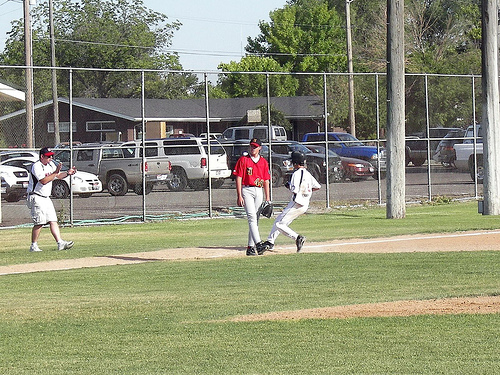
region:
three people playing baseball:
[12, 120, 353, 283]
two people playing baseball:
[213, 116, 340, 296]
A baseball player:
[217, 123, 275, 255]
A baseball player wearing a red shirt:
[225, 128, 277, 255]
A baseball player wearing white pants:
[219, 130, 271, 271]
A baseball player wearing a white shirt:
[271, 125, 320, 269]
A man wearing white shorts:
[17, 137, 81, 277]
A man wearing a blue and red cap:
[20, 138, 77, 245]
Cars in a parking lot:
[54, 121, 234, 204]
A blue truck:
[307, 117, 401, 185]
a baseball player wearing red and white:
[227, 132, 272, 257]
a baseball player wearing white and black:
[264, 149, 320, 261]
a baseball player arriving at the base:
[261, 148, 319, 264]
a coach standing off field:
[21, 146, 75, 256]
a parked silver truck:
[54, 139, 169, 194]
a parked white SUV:
[106, 136, 228, 191]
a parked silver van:
[217, 121, 288, 144]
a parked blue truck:
[298, 127, 390, 174]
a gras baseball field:
[8, 231, 492, 373]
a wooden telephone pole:
[384, 0, 409, 222]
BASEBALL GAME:
[22, 95, 389, 318]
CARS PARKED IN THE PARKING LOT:
[9, 39, 476, 212]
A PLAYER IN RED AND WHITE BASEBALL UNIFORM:
[216, 116, 273, 271]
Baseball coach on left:
[20, 119, 394, 287]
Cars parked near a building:
[24, 65, 417, 195]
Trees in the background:
[15, 2, 499, 194]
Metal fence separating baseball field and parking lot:
[8, 46, 494, 242]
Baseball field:
[22, 110, 413, 372]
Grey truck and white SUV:
[65, 125, 229, 192]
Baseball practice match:
[25, 125, 397, 292]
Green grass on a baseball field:
[161, 335, 342, 373]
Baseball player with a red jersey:
[235, 152, 271, 187]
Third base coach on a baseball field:
[18, 144, 89, 256]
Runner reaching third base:
[275, 150, 324, 252]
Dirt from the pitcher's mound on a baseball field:
[236, 292, 488, 322]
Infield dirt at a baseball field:
[414, 230, 496, 254]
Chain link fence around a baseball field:
[68, 62, 205, 216]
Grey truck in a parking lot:
[60, 143, 171, 193]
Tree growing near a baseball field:
[11, 8, 206, 96]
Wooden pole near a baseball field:
[386, 0, 408, 214]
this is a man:
[233, 135, 273, 264]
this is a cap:
[249, 136, 259, 146]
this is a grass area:
[86, 271, 246, 373]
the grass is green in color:
[150, 275, 184, 290]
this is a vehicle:
[168, 135, 222, 184]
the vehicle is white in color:
[177, 158, 201, 170]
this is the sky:
[189, 8, 231, 46]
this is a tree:
[280, 12, 331, 62]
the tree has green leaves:
[276, 16, 302, 47]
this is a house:
[73, 91, 203, 128]